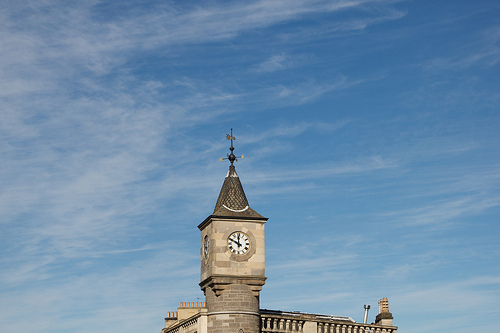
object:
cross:
[225, 128, 236, 141]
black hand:
[237, 235, 240, 247]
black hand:
[228, 237, 242, 247]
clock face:
[233, 233, 246, 252]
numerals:
[229, 238, 233, 242]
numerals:
[237, 251, 239, 255]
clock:
[227, 230, 251, 254]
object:
[374, 297, 392, 327]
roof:
[260, 309, 356, 323]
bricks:
[212, 220, 265, 277]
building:
[159, 128, 397, 332]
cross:
[218, 154, 244, 164]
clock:
[204, 235, 210, 260]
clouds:
[2, 2, 67, 51]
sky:
[1, 0, 500, 121]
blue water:
[281, 202, 323, 235]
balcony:
[258, 315, 399, 333]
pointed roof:
[212, 165, 270, 219]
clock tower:
[197, 127, 266, 311]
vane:
[226, 134, 237, 141]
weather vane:
[219, 127, 244, 163]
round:
[222, 226, 257, 262]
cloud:
[397, 183, 498, 231]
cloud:
[427, 50, 487, 80]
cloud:
[392, 271, 496, 316]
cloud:
[254, 43, 299, 78]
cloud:
[280, 224, 364, 272]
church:
[157, 128, 399, 333]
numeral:
[233, 234, 237, 238]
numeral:
[242, 235, 245, 238]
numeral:
[244, 247, 248, 250]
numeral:
[233, 249, 237, 253]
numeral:
[246, 243, 249, 245]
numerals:
[228, 242, 233, 245]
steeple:
[197, 127, 269, 297]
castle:
[156, 127, 401, 333]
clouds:
[10, 11, 170, 228]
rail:
[260, 312, 398, 333]